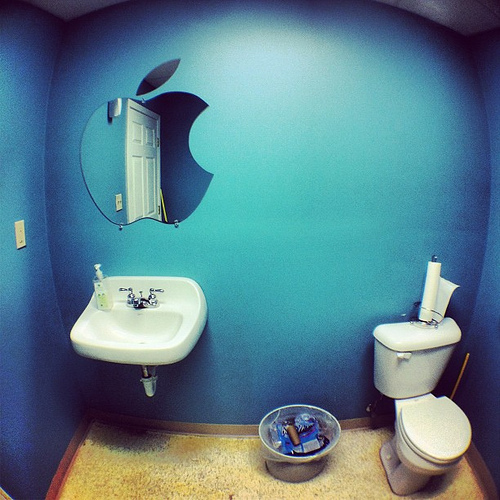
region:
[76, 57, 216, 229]
apple shaped glass mirror on the wall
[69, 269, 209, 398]
white bathroom sink with silver faucets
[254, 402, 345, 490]
full bathroom garbage can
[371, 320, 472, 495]
white toilet with the lid closed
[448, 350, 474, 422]
brown plunger handle behind the toilet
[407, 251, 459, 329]
paper towel holder and roll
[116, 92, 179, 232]
white door reflection in the mirror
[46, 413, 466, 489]
dirty yellow linoleum floor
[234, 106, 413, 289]
blue bathroom wall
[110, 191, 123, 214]
off white light switch reflected in the mirror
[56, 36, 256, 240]
A large apple shaped mirror.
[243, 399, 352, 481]
a bathroom trash can.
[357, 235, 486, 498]
A white toilet in a restroom.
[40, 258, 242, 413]
A white sink in a bathroom.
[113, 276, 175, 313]
A metal faucet in a sink.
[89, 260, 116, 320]
hand soap on the side of a sink.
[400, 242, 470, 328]
A roll of paper towels on a tank.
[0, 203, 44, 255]
A light switch.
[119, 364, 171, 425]
bathroom sink drain.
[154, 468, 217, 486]
tiled bathroom floor.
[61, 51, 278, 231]
A apple mirror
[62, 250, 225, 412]
A white sink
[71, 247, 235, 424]
Soap sitting next to a sink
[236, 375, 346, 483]
A bathroom trash can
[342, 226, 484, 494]
A white toilet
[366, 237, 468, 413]
Paper towels on top of a toilet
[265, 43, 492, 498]
A blue bathroom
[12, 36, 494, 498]
A bathroom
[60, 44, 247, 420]
A mirror above a sink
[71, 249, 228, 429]
The faucet is not running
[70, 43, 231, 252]
The mirror is an apple.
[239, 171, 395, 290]
The wall is blue.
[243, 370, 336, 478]
The trash is full.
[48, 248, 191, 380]
The sink is white.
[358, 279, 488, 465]
The toilet is white.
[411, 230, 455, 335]
The paper towel is white.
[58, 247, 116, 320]
Soap on the sink.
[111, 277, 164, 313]
Faucet is white.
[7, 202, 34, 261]
The switch is beige.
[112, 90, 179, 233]
The door is white.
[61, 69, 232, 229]
An apple shaped mirror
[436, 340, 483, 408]
The handle of a toilet plunger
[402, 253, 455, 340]
Paper towels on the back of a toilet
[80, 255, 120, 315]
A liquid soap dispenser on a sink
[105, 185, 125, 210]
A light switch reflected in a mirror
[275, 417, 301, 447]
An empty toilet paper roll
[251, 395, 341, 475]
A bag lined trash can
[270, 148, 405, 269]
A blue painted wall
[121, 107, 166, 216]
A white door reflected in a mirror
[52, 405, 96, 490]
A brown wood floor board